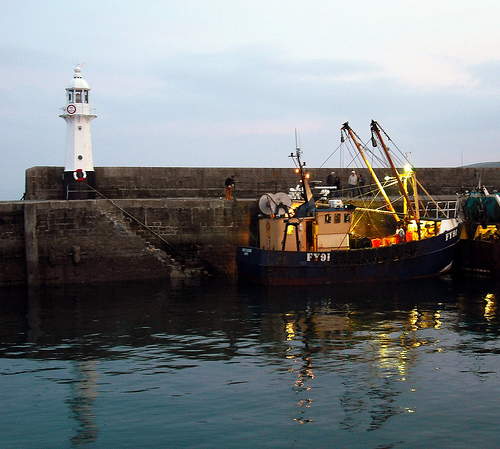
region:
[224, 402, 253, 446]
the water is clear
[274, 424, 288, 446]
the water is clear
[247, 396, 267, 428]
the water is clear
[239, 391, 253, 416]
the water is clear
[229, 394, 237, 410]
the water is clear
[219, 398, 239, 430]
the water is clear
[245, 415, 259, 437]
the water is clear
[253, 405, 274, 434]
the water is clear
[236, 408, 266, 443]
the water is clear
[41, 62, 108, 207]
small white and black light house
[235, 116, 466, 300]
dark blue commercial fishing boat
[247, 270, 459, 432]
reflection of a fishing boat in the water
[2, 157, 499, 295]
weathered grey concrete wall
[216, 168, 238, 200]
man wearing orange pants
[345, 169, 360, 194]
man wearing a white shirt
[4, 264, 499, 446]
slightly rippled calm blue water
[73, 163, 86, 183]
red and white life saver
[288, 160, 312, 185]
orange coloured lights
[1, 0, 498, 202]
grey over cast sky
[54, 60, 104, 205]
a glowing white light house.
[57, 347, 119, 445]
a reflection of a light house.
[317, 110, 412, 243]
a crane near a body of water.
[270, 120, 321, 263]
a tall crane on a dock.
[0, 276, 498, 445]
a body of water near a pier.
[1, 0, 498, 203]
a gray cloudy sky.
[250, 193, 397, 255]
a building near a pier.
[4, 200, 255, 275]
a large wooden structure.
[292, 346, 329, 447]
a reflection of a crane.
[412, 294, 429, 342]
a light reflecting on water.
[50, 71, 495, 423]
lighthouse with boats nearby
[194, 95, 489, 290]
small blue boat on water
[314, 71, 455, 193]
yellow cranes by boat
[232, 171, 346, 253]
small room on top of boat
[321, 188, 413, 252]
lights coming off of a boat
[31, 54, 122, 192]
small white light house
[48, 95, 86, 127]
red sign on side of house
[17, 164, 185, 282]
stairs leading up from dock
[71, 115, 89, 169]
two small windows on lighthouse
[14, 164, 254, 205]
metal fence on side of dock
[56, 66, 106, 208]
black and white lighthouse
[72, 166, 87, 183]
red and white innertube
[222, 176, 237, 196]
man wearing black jacket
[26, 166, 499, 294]
grey stone wall barrier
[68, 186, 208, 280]
grey metal stairs railing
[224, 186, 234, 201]
orange fisherman pants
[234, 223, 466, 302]
blue and white fishing boat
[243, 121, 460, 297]
boat docked at wall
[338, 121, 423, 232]
yellow painted boat crane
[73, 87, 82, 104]
glass window in lighthouse